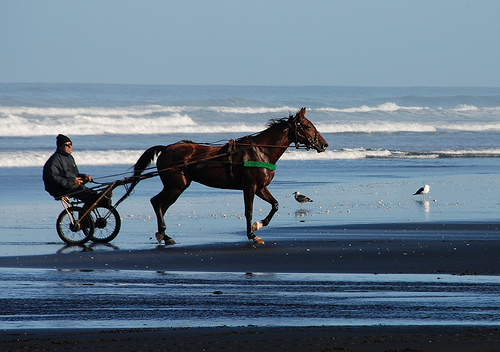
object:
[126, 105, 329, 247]
horse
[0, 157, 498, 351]
beach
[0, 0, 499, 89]
sky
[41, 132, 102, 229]
man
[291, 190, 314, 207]
bird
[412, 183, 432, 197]
bird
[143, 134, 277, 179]
harness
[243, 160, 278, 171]
strap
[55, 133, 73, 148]
stocking cap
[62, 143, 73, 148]
sunglasses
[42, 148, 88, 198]
windbreaker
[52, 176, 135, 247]
carriage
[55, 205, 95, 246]
wheel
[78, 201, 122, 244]
wheel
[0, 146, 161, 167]
waves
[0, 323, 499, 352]
part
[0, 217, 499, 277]
part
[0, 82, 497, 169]
ocean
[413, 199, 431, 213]
reflection